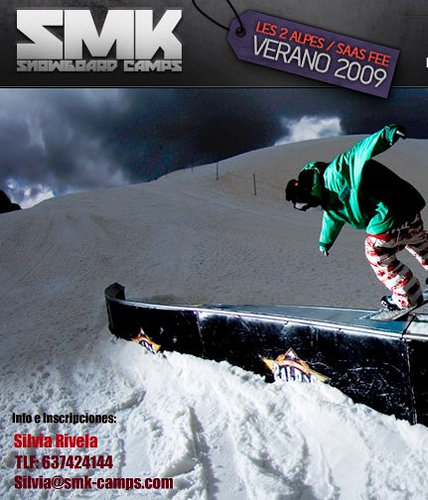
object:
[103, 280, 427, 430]
rail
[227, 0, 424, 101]
tag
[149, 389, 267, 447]
map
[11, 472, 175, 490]
website adress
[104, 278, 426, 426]
ski ramp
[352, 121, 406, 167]
arm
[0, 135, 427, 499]
snow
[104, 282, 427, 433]
metal rail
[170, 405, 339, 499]
snow tracks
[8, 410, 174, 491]
writings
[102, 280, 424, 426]
platform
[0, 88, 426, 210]
sky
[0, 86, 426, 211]
clouds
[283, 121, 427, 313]
snowboarder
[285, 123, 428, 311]
person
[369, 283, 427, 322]
snowboard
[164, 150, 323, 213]
fence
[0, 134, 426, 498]
hill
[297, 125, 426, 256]
jacket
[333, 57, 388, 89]
2009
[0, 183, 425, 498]
tracks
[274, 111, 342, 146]
cloud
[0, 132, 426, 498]
ground